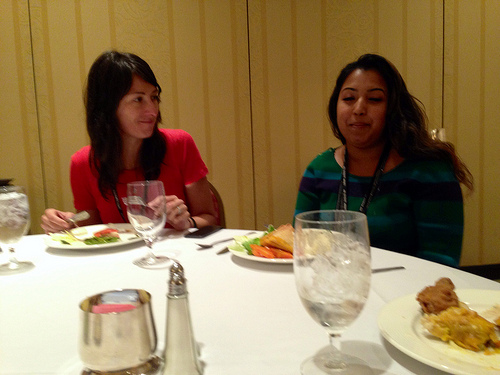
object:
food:
[251, 243, 279, 259]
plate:
[227, 225, 344, 265]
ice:
[308, 261, 363, 294]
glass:
[292, 201, 373, 374]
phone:
[183, 218, 225, 240]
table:
[0, 222, 500, 374]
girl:
[38, 47, 228, 246]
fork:
[120, 188, 177, 241]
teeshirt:
[65, 126, 209, 226]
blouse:
[291, 143, 465, 267]